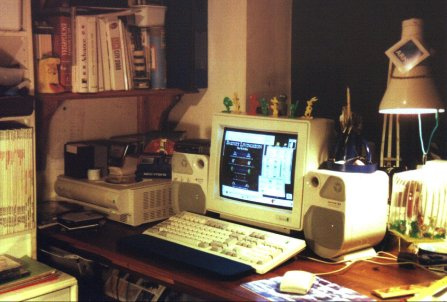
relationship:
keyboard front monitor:
[148, 203, 311, 277] [196, 100, 337, 234]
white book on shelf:
[33, 4, 169, 93] [39, 88, 179, 111]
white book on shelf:
[101, 22, 129, 86] [39, 88, 179, 111]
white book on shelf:
[33, 4, 169, 93] [37, 82, 174, 113]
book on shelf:
[80, 18, 106, 90] [31, 82, 164, 133]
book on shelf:
[105, 17, 128, 88] [36, 86, 200, 131]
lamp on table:
[378, 15, 444, 114] [39, 202, 443, 300]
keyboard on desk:
[143, 210, 309, 275] [43, 160, 445, 299]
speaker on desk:
[300, 148, 395, 284] [41, 218, 445, 300]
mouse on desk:
[279, 270, 316, 295] [45, 207, 446, 300]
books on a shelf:
[33, 7, 170, 90] [29, 0, 206, 96]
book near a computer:
[72, 9, 86, 92] [148, 105, 387, 281]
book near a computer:
[85, 17, 100, 90] [148, 105, 387, 281]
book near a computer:
[96, 17, 111, 89] [148, 105, 387, 281]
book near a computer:
[105, 17, 128, 88] [148, 105, 387, 281]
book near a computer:
[56, 16, 75, 91] [148, 105, 387, 281]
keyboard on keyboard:
[143, 210, 309, 275] [143, 203, 294, 259]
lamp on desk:
[378, 18, 446, 114] [329, 264, 420, 287]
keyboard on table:
[143, 210, 309, 275] [39, 202, 443, 300]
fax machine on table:
[54, 174, 172, 226] [39, 202, 443, 300]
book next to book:
[75, 14, 89, 97] [49, 13, 72, 88]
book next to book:
[75, 14, 89, 97] [104, 17, 126, 89]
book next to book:
[75, 14, 89, 97] [99, 19, 109, 87]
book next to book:
[75, 14, 89, 97] [87, 13, 97, 92]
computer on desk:
[115, 112, 337, 281] [43, 160, 445, 299]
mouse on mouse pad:
[279, 270, 316, 295] [243, 262, 369, 300]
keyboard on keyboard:
[143, 210, 309, 275] [148, 203, 311, 277]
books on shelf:
[58, 14, 136, 91] [29, 0, 206, 96]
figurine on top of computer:
[223, 94, 318, 120] [133, 82, 359, 281]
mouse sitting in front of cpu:
[275, 265, 317, 295] [301, 157, 393, 257]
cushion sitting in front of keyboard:
[111, 229, 254, 298] [146, 197, 313, 252]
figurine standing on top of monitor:
[223, 94, 318, 120] [194, 98, 325, 242]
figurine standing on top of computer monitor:
[223, 94, 318, 120] [207, 109, 330, 232]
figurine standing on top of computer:
[223, 94, 318, 120] [148, 105, 387, 281]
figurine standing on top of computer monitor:
[223, 94, 318, 120] [206, 112, 311, 232]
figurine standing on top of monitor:
[223, 94, 318, 120] [204, 109, 336, 232]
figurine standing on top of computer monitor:
[223, 94, 318, 120] [205, 111, 315, 235]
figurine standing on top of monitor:
[303, 96, 317, 120] [204, 109, 336, 232]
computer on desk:
[142, 107, 334, 272] [269, 260, 440, 297]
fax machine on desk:
[39, 174, 171, 233] [45, 179, 437, 286]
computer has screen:
[115, 112, 337, 281] [213, 120, 300, 211]